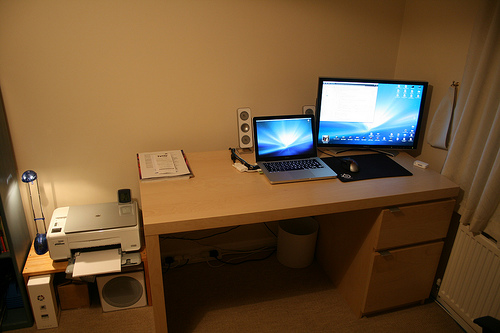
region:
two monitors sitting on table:
[250, 67, 426, 170]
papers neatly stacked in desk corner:
[127, 127, 212, 187]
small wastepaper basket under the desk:
[265, 212, 321, 279]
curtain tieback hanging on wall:
[421, 72, 461, 152]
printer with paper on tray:
[40, 186, 140, 281]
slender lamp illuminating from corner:
[10, 160, 55, 270]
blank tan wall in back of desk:
[52, 20, 383, 135]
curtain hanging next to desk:
[445, 25, 495, 246]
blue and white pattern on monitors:
[233, 78, 445, 171]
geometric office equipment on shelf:
[25, 262, 165, 322]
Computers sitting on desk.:
[246, 67, 449, 184]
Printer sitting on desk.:
[46, 195, 143, 258]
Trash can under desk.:
[275, 216, 322, 272]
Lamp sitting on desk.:
[18, 166, 47, 258]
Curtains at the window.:
[441, 63, 499, 234]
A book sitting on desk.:
[133, 143, 200, 188]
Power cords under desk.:
[164, 235, 270, 270]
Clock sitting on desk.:
[231, 104, 256, 159]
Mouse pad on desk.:
[326, 155, 411, 186]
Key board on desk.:
[256, 156, 335, 187]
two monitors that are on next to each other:
[246, 56, 436, 189]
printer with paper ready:
[44, 193, 144, 284]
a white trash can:
[272, 212, 334, 280]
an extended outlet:
[156, 245, 255, 273]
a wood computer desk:
[116, 133, 467, 315]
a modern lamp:
[14, 163, 53, 268]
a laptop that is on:
[249, 107, 339, 187]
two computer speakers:
[232, 97, 317, 153]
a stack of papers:
[133, 144, 197, 181]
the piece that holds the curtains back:
[427, 75, 462, 160]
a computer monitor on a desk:
[308, 70, 438, 153]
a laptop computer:
[246, 113, 336, 195]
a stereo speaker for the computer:
[228, 97, 266, 160]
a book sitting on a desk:
[132, 127, 206, 199]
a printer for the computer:
[35, 176, 159, 290]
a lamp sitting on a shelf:
[8, 154, 58, 278]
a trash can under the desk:
[263, 208, 347, 285]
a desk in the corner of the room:
[137, 110, 470, 329]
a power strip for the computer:
[156, 235, 240, 284]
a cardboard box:
[46, 272, 98, 316]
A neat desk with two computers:
[12, 27, 460, 317]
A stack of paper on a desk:
[131, 141, 204, 203]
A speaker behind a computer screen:
[229, 101, 280, 151]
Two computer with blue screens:
[251, 76, 429, 162]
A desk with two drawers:
[146, 182, 443, 322]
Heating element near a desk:
[381, 192, 497, 312]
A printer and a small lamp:
[17, 167, 141, 269]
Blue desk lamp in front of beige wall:
[13, 166, 46, 256]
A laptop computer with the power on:
[251, 116, 338, 184]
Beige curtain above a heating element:
[461, 153, 494, 300]